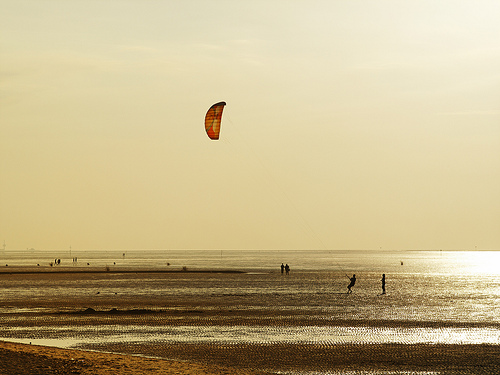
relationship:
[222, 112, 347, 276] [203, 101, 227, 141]
string of kite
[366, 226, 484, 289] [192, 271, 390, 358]
suns reflection on water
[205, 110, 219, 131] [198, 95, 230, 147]
design on kite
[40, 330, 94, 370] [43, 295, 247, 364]
sand on beach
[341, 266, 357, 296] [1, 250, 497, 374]
people on beach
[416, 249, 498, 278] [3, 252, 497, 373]
sun on water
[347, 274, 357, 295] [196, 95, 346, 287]
people flying kite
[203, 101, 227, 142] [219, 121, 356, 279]
kite to string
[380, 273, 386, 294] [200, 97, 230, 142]
people watching kite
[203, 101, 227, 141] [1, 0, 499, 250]
kite in sky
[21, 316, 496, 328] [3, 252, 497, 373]
wave on water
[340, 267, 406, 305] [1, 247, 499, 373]
people in ocean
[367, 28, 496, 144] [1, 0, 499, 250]
clouds in sky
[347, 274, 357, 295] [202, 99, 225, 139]
people flying kite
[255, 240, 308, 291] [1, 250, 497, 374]
people on beach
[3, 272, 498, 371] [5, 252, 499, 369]
beach full of sand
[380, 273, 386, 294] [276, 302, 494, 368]
people in water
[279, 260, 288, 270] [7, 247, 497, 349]
people standing in ocean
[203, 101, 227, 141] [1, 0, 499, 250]
kite flying in sky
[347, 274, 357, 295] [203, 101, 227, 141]
people flying kite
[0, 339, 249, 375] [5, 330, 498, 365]
sand covering ground